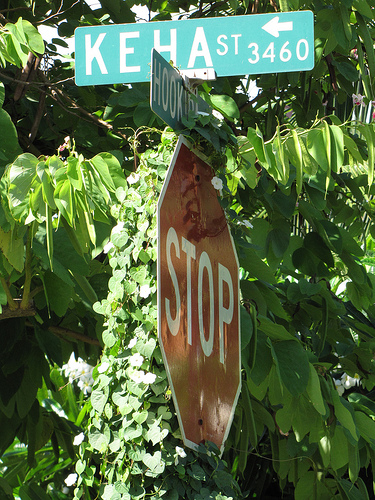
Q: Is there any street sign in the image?
A: Yes, there is a street sign.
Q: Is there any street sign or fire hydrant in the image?
A: Yes, there is a street sign.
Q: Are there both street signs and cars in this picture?
A: No, there is a street sign but no cars.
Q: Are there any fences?
A: No, there are no fences.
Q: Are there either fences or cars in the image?
A: No, there are no fences or cars.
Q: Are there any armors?
A: No, there are no armors.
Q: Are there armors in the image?
A: No, there are no armors.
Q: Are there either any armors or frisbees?
A: No, there are no armors or frisbees.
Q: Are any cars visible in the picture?
A: No, there are no cars.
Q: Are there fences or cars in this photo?
A: No, there are no cars or fences.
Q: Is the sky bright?
A: Yes, the sky is bright.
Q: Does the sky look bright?
A: Yes, the sky is bright.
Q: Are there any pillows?
A: No, there are no pillows.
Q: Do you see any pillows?
A: No, there are no pillows.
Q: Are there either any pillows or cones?
A: No, there are no pillows or cones.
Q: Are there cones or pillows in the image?
A: No, there are no pillows or cones.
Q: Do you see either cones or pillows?
A: No, there are no pillows or cones.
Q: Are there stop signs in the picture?
A: Yes, there is a stop sign.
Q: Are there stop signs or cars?
A: Yes, there is a stop sign.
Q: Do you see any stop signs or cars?
A: Yes, there is a stop sign.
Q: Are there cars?
A: No, there are no cars.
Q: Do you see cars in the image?
A: No, there are no cars.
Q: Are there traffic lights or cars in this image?
A: No, there are no cars or traffic lights.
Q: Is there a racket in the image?
A: No, there are no rackets.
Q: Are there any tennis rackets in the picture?
A: No, there are no tennis rackets.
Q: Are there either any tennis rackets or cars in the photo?
A: No, there are no tennis rackets or cars.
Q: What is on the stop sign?
A: The graffiti is on the stop sign.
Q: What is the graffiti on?
A: The graffiti is on the stop sign.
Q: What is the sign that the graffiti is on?
A: The sign is a stop sign.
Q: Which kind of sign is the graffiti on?
A: The graffiti is on the stop sign.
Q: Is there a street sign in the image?
A: Yes, there is a street sign.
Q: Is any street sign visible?
A: Yes, there is a street sign.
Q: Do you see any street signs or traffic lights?
A: Yes, there is a street sign.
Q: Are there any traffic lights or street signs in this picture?
A: Yes, there is a street sign.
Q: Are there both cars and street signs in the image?
A: No, there is a street sign but no cars.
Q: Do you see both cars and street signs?
A: No, there is a street sign but no cars.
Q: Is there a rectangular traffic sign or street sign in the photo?
A: Yes, there is a rectangular street sign.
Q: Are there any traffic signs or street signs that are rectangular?
A: Yes, the street sign is rectangular.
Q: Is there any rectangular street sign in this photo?
A: Yes, there is a rectangular street sign.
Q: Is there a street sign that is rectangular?
A: Yes, there is a street sign that is rectangular.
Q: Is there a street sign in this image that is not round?
A: Yes, there is a rectangular street sign.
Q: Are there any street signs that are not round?
A: Yes, there is a rectangular street sign.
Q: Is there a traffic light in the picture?
A: No, there are no traffic lights.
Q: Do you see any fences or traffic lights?
A: No, there are no traffic lights or fences.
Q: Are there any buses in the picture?
A: No, there are no buses.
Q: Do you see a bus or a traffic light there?
A: No, there are no buses or traffic lights.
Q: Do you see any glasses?
A: No, there are no glasses.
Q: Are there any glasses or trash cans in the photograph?
A: No, there are no glasses or trash cans.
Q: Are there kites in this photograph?
A: No, there are no kites.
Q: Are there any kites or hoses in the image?
A: No, there are no kites or hoses.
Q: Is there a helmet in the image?
A: No, there are no helmets.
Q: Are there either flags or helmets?
A: No, there are no helmets or flags.